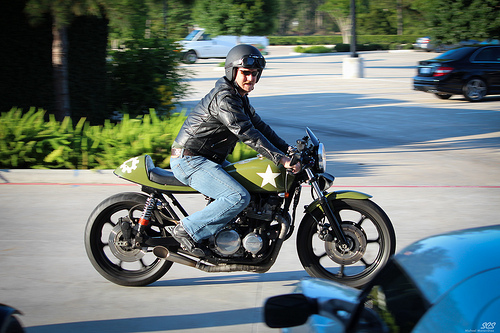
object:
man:
[168, 45, 302, 254]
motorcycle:
[83, 126, 397, 286]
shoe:
[165, 224, 206, 258]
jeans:
[169, 149, 252, 243]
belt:
[171, 148, 202, 156]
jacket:
[174, 74, 290, 166]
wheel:
[82, 190, 179, 286]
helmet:
[225, 44, 267, 83]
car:
[412, 42, 499, 101]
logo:
[256, 164, 281, 188]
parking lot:
[0, 45, 499, 332]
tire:
[462, 76, 489, 102]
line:
[0, 181, 499, 190]